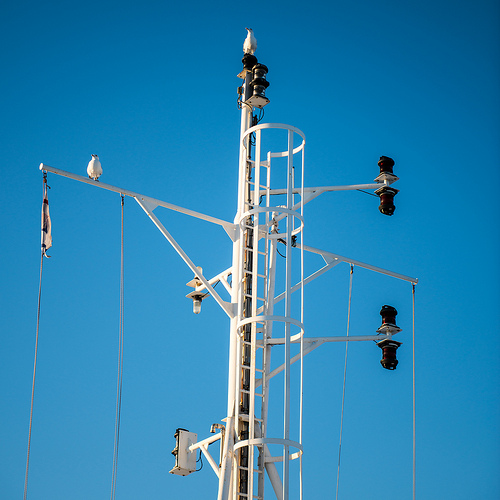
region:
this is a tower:
[13, 18, 470, 485]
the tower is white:
[38, 23, 456, 498]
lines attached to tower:
[26, 137, 433, 494]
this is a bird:
[68, 149, 131, 187]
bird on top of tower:
[5, 20, 490, 493]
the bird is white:
[71, 139, 108, 194]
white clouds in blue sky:
[55, 45, 96, 79]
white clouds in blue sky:
[355, 379, 397, 406]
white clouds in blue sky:
[401, 428, 471, 498]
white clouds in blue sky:
[332, 442, 397, 490]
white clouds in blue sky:
[50, 341, 97, 389]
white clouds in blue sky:
[77, 455, 114, 475]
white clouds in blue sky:
[95, 299, 156, 339]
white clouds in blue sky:
[327, 23, 368, 58]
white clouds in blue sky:
[70, 53, 110, 84]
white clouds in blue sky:
[34, 22, 103, 65]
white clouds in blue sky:
[14, 393, 46, 441]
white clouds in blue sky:
[322, 453, 383, 495]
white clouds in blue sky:
[382, 442, 442, 494]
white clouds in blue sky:
[322, 386, 407, 441]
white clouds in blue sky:
[100, 341, 125, 368]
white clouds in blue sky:
[24, 396, 102, 443]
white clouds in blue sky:
[408, 52, 488, 112]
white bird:
[85, 143, 110, 191]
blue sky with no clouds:
[27, 49, 64, 95]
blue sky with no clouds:
[315, 452, 361, 493]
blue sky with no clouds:
[41, 414, 97, 459]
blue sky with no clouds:
[144, 42, 183, 106]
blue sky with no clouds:
[27, 46, 63, 70]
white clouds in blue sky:
[351, 419, 389, 450]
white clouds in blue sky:
[0, 373, 50, 420]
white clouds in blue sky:
[20, 38, 47, 62]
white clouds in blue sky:
[50, 31, 110, 88]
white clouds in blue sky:
[394, 405, 442, 447]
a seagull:
[84, 146, 102, 183]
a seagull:
[236, 20, 260, 60]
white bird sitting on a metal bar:
[85, 150, 104, 184]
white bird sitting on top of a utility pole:
[238, 22, 258, 57]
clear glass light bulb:
[191, 293, 203, 316]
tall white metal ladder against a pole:
[220, 120, 272, 498]